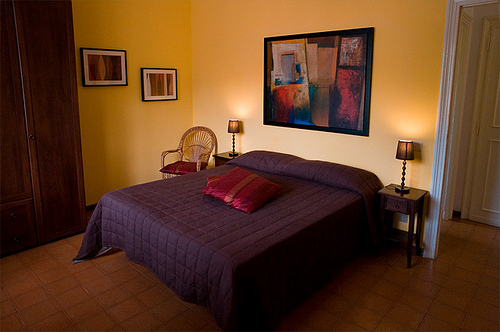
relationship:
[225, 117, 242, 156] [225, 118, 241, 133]
lamp has shade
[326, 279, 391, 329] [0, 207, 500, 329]
tile on floor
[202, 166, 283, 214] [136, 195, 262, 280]
pillow on bed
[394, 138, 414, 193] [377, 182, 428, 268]
lamp on right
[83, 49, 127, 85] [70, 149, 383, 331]
painting hanging over bed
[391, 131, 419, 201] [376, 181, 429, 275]
lamp on table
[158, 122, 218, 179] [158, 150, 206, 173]
chair has red cushion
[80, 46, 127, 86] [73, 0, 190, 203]
painting on wall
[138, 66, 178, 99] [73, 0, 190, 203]
painting on wall